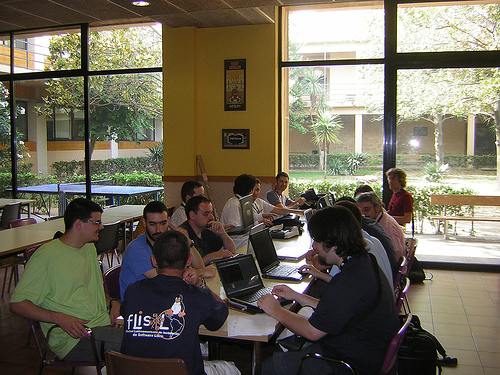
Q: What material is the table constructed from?
A: Wood.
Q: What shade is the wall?
A: Yellow.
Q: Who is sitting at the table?
A: A group of men.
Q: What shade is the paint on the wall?
A: Yellow.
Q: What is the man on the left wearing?
A: A green shirt.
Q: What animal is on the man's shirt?
A: A penguin.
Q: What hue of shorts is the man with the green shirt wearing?
A: Grey.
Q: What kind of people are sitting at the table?
A: Men with laptop computers.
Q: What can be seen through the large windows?
A: A garden.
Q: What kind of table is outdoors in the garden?
A: A ping pong table.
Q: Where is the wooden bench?
A: Outside by the garden.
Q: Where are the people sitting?
A: Large table.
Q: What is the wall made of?
A: Wood.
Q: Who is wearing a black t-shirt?
A: Man in center front.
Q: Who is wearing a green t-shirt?
A: Man with glasses.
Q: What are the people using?
A: Laptops.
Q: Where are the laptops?
A: On table.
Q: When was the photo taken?
A: Sunny day.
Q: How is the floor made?
A: Tiled.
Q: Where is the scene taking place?
A: A school.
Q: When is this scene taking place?
A: Afternoon.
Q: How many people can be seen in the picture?
A: 14.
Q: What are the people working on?
A: Laptops.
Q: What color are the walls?
A: Yellow.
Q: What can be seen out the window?
A: A park area.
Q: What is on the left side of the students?
A: A long table.